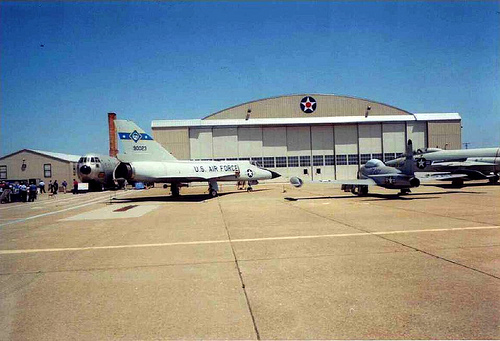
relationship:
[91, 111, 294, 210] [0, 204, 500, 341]
plane on floor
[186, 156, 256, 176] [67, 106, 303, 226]
writing on plane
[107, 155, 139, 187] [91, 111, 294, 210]
afterburner on plane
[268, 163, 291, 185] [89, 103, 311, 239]
nose of plane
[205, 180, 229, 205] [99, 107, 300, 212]
wheel of plane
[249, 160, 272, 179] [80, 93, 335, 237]
cockpit of plane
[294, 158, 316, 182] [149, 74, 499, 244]
window on building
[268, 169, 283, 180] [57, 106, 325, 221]
nose of plane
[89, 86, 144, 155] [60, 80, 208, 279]
stripe on tail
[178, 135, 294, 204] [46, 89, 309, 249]
words on plane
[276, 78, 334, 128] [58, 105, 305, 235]
sign on plane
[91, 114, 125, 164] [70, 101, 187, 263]
numbers on tail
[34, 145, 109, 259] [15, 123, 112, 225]
people in front of building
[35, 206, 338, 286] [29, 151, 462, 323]
line on floor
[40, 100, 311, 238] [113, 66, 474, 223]
plane in front of building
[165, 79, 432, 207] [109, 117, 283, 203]
building behind plane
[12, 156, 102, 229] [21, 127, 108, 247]
people in front of building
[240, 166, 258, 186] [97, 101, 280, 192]
logotype on side of plane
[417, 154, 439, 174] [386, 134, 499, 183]
logotype on side of plane